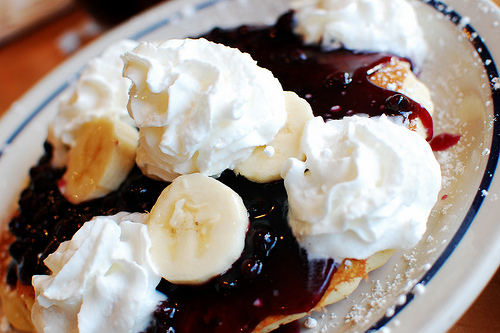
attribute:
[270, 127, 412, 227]
whipped ceam — white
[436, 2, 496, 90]
rim — blue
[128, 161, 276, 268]
slice — small, round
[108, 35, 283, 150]
whipped cream — dollop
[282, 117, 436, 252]
whipped cream — dollop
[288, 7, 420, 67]
whipped cream — dollop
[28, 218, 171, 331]
whipped cream — dollop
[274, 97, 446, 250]
cream — white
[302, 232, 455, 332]
sugar — powdered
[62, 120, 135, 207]
banana — yellow, sliced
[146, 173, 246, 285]
banana — yellow, sliced, slice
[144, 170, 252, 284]
banana — slice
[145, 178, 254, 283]
banana — yellow, sliced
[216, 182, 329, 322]
blueberry sauce — dark, thick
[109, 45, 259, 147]
cream — dollop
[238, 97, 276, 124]
cream — white, thick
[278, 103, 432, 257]
cream — whipped, dollop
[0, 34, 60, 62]
table — brown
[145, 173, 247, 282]
banana slice — slimey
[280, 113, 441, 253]
cream — whipped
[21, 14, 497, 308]
plate — white, round